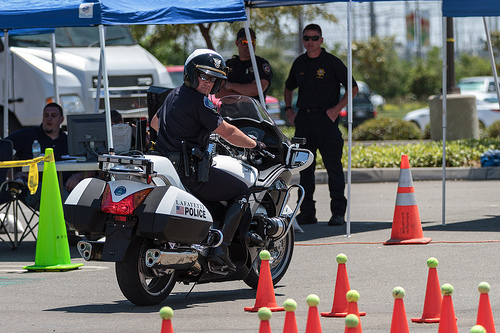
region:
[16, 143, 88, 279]
THIS CONE IS LARGE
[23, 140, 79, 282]
THIS CONE IS GREEN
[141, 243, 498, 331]
THESE CONES ARE SMALL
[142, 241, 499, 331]
THESE CONES ARE ORANGE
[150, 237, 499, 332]
THE BALLS ARE ON TOP OF THE SMALL CONES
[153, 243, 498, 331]
THE BALLS ARE YELLOW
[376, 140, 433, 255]
THIS CONE HAS REFLECTIVE TAPE ON IT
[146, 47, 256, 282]
THIS IS A POLICE OFFICER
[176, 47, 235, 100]
THIS OFFICER IS WEARING A HELMET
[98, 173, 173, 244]
THIS IS THE TAIL LIGHT OF THE MOTORCYCLE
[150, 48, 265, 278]
officer on police motorcycle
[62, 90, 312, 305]
white and black police motorcycle near orange cones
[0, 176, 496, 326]
black asphalt paved parking lot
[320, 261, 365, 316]
small orange cone with ball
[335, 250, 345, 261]
bright green ball on cone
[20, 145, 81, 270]
bright green cone behind motorcycle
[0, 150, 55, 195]
yellow police tape tied to green cone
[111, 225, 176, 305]
small black rubber tire on motorcycle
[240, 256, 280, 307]
small orange cone near motorcycle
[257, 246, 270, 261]
green ball on top of orange cone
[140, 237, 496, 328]
THE BALLS ARE TENNIS BALLS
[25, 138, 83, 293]
THIS CONE IS BRIGHT GREEN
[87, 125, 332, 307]
THIS IS A POLICE MOTORCYCLE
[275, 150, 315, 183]
THIS IS A SIDE MIRROR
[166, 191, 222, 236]
THE BIKE SAYS POLICE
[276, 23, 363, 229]
THE MAN IS STANDING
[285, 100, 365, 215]
THE MAN IS WEARING BLACK PANTS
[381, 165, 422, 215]
THE CONE HAS REFLECTIVE TAPE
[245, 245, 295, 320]
THE CONE IS ORANGE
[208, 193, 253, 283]
THIS MAN IS WEARING BLACK BOOTS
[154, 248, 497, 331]
orange cones topped with tennis balls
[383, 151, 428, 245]
a medium orange cone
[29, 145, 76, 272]
a bright yellow-green cone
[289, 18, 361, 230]
an officer with hands in pockets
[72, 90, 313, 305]
a motorcycle with police decal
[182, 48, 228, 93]
a whtie and black police helmet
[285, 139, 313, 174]
rearview mirror on motorcycle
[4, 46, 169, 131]
a pull-along trailer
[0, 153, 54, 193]
a string of yellow caution tape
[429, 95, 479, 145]
a concrete base of a pole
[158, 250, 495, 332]
Small traffic cones with tennis balls on the top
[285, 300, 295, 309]
A yellow tennis ball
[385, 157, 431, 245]
A large traffic cone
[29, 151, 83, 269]
A large yellow traffic cone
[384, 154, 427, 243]
A large orange traffic cone with white stripes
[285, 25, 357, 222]
A young man standing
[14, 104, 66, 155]
A person sitting down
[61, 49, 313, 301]
A a black and white police issue motorcycle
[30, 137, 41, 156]
A small bottle of water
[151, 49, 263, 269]
A police officer on a motorcycle